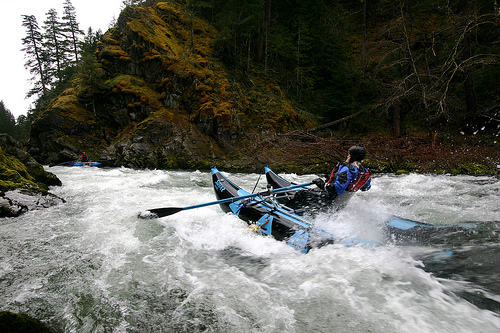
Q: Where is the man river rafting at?
A: River.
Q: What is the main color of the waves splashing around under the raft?
A: White.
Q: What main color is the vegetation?
A: Green.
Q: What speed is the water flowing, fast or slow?
A: Fast.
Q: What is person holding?
A: Paddle.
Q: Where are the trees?
A: On the hill.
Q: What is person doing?
A: White water rafting.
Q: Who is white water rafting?
A: The person.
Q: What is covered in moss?
A: Large rocks.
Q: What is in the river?
A: White water.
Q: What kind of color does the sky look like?
A: White.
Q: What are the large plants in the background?
A: Trees.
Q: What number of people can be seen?
A: Two.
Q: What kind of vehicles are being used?
A: Boats.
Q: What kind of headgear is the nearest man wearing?
A: A helmet.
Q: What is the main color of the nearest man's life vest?
A: Red.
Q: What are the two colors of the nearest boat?
A: Black and blue.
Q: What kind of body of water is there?
A: A river.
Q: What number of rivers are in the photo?
A: One.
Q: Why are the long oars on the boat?
A: Additional control of pontoon.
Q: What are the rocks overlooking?
A: The river.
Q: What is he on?
A: A catamaran raft.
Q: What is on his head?
A: A helmet.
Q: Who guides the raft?
A: A raft rider.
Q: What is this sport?
A: Extreme rafting.